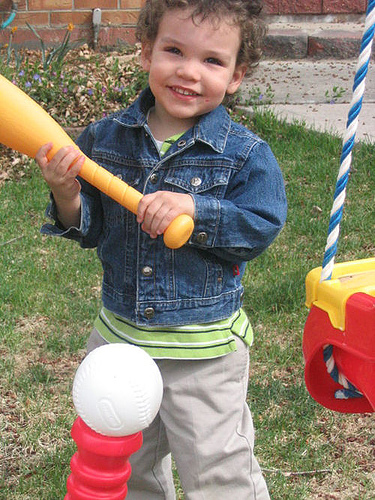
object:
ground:
[0, 45, 373, 500]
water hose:
[0, 1, 24, 34]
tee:
[61, 421, 143, 499]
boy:
[38, 5, 286, 500]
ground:
[316, 98, 337, 115]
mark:
[205, 99, 210, 102]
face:
[139, 0, 245, 120]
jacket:
[43, 92, 286, 326]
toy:
[61, 337, 165, 498]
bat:
[0, 74, 199, 245]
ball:
[70, 340, 165, 438]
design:
[131, 342, 151, 429]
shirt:
[95, 301, 257, 364]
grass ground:
[0, 143, 375, 500]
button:
[197, 231, 210, 246]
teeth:
[167, 86, 205, 101]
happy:
[135, 0, 262, 117]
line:
[321, 0, 375, 281]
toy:
[302, 0, 374, 415]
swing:
[301, 255, 373, 413]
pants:
[81, 336, 271, 500]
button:
[190, 176, 202, 188]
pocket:
[165, 167, 229, 194]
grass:
[0, 117, 375, 500]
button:
[142, 266, 153, 276]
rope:
[317, 0, 375, 283]